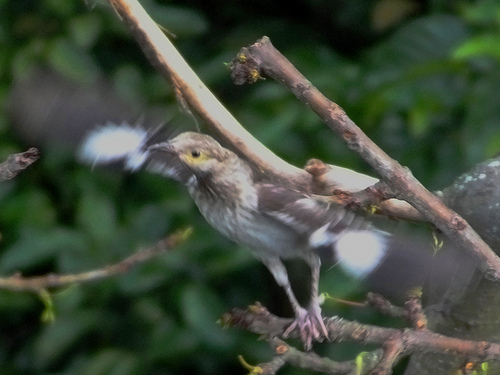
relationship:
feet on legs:
[284, 309, 329, 345] [270, 253, 327, 314]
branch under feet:
[235, 291, 500, 374] [284, 309, 329, 345]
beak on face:
[148, 138, 171, 154] [174, 137, 207, 175]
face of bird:
[174, 137, 207, 175] [90, 112, 396, 336]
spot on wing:
[80, 113, 149, 170] [72, 112, 208, 208]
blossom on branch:
[234, 346, 266, 375] [235, 291, 500, 374]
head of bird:
[145, 126, 220, 179] [90, 112, 396, 336]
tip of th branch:
[213, 299, 276, 340] [235, 291, 500, 374]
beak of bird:
[148, 138, 171, 154] [90, 112, 396, 336]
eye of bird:
[190, 150, 203, 161] [90, 112, 396, 336]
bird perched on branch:
[90, 112, 396, 336] [235, 291, 500, 374]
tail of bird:
[323, 209, 480, 295] [90, 112, 396, 336]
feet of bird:
[284, 309, 329, 345] [90, 112, 396, 336]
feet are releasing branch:
[284, 309, 329, 345] [235, 291, 500, 374]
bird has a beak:
[90, 112, 396, 336] [148, 138, 171, 154]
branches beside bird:
[113, 6, 500, 374] [90, 112, 396, 336]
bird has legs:
[90, 112, 396, 336] [270, 253, 327, 314]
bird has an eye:
[90, 112, 396, 336] [190, 150, 203, 161]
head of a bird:
[145, 126, 220, 179] [90, 112, 396, 336]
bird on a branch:
[90, 112, 396, 336] [235, 291, 500, 374]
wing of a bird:
[72, 112, 208, 208] [90, 112, 396, 336]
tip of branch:
[213, 299, 276, 340] [235, 291, 500, 374]